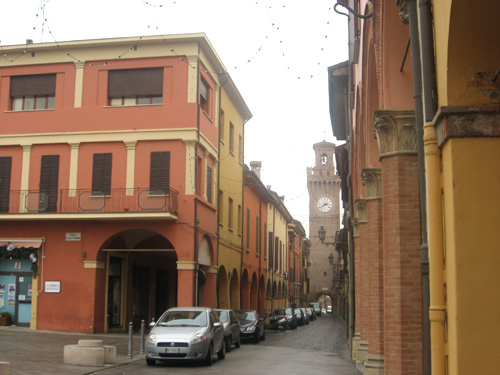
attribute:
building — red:
[0, 37, 311, 315]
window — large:
[9, 75, 56, 110]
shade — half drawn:
[13, 76, 53, 95]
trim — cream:
[2, 33, 222, 224]